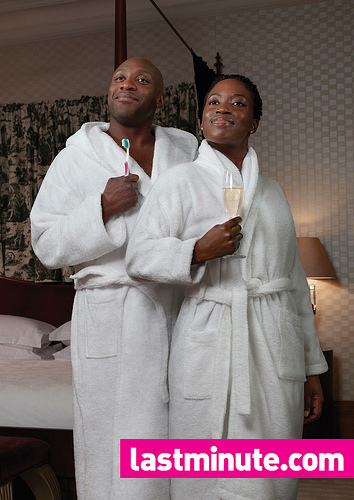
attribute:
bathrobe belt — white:
[183, 277, 293, 416]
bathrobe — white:
[124, 138, 328, 498]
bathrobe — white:
[29, 120, 197, 498]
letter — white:
[185, 451, 211, 473]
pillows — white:
[8, 310, 74, 363]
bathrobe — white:
[87, 113, 349, 409]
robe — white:
[42, 152, 168, 497]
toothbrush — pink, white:
[119, 137, 130, 177]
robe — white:
[124, 139, 322, 439]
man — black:
[27, 53, 206, 498]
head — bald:
[108, 55, 164, 121]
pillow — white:
[0, 310, 49, 349]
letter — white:
[159, 450, 174, 479]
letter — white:
[210, 443, 218, 473]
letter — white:
[218, 450, 235, 471]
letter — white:
[234, 451, 251, 471]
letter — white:
[251, 446, 263, 472]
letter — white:
[263, 451, 280, 471]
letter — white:
[104, 435, 142, 482]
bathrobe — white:
[71, 135, 229, 470]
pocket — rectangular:
[80, 281, 136, 367]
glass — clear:
[223, 170, 246, 260]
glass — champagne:
[221, 161, 258, 269]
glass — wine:
[215, 168, 249, 264]